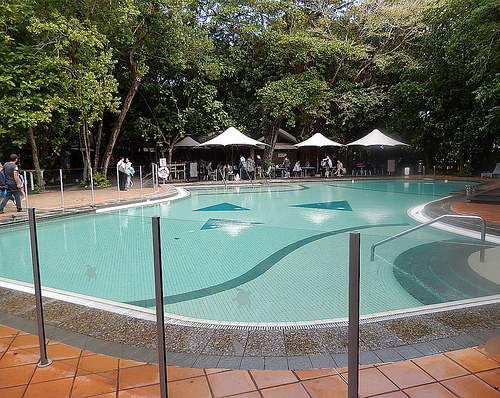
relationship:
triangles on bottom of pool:
[202, 217, 264, 234] [1, 176, 500, 337]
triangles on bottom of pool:
[192, 199, 254, 215] [1, 176, 500, 337]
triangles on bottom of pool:
[290, 198, 357, 218] [1, 176, 500, 337]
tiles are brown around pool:
[1, 326, 499, 397] [1, 176, 500, 337]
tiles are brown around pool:
[454, 200, 500, 222] [1, 176, 500, 337]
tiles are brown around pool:
[410, 170, 498, 189] [1, 176, 500, 337]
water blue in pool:
[1, 183, 496, 322] [1, 176, 500, 337]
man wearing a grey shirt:
[2, 152, 32, 214] [5, 163, 19, 187]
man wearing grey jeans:
[2, 152, 32, 214] [0, 187, 22, 214]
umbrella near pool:
[199, 125, 269, 176] [1, 176, 500, 337]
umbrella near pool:
[174, 129, 200, 170] [1, 176, 500, 337]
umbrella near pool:
[297, 127, 346, 177] [1, 176, 500, 337]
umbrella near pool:
[349, 126, 408, 176] [1, 176, 500, 337]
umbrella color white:
[174, 129, 200, 170] [225, 133, 242, 141]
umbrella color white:
[297, 127, 346, 177] [225, 133, 242, 141]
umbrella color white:
[349, 126, 408, 176] [225, 133, 242, 141]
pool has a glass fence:
[1, 176, 500, 337] [2, 209, 500, 397]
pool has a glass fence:
[1, 176, 500, 337] [6, 164, 162, 205]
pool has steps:
[1, 176, 500, 337] [398, 230, 499, 302]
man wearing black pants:
[117, 158, 130, 190] [119, 173, 128, 193]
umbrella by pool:
[174, 129, 200, 170] [1, 176, 500, 337]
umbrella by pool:
[199, 125, 269, 176] [1, 176, 500, 337]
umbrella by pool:
[297, 127, 346, 177] [1, 176, 500, 337]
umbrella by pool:
[349, 126, 408, 176] [1, 176, 500, 337]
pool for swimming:
[1, 176, 500, 337] [186, 195, 363, 286]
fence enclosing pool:
[2, 209, 500, 397] [1, 176, 500, 337]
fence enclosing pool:
[6, 164, 162, 205] [1, 176, 500, 337]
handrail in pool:
[366, 211, 490, 264] [1, 176, 500, 337]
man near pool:
[117, 157, 129, 191] [1, 176, 500, 337]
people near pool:
[2, 152, 32, 214] [1, 176, 500, 337]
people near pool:
[178, 153, 352, 179] [1, 176, 500, 337]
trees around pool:
[0, 4, 500, 178] [1, 176, 500, 337]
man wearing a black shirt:
[2, 152, 32, 214] [5, 163, 19, 187]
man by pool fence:
[117, 157, 129, 191] [2, 209, 500, 397]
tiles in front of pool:
[1, 326, 499, 397] [1, 176, 500, 337]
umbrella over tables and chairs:
[297, 127, 346, 177] [294, 169, 304, 177]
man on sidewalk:
[117, 157, 129, 191] [1, 172, 164, 222]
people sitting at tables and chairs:
[178, 153, 352, 179] [174, 163, 399, 178]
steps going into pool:
[398, 230, 499, 302] [1, 176, 500, 337]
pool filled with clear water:
[1, 176, 500, 337] [1, 183, 496, 322]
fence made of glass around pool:
[6, 164, 162, 205] [1, 176, 500, 337]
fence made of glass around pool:
[2, 209, 500, 397] [1, 176, 500, 337]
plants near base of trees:
[81, 172, 107, 188] [0, 4, 500, 178]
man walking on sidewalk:
[2, 152, 32, 214] [1, 172, 164, 222]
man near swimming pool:
[117, 157, 129, 191] [1, 176, 500, 337]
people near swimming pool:
[178, 153, 352, 179] [1, 176, 500, 337]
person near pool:
[2, 152, 32, 214] [1, 176, 500, 337]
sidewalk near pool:
[1, 172, 164, 222] [1, 176, 500, 337]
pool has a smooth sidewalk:
[1, 176, 500, 337] [1, 172, 164, 222]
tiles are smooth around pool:
[1, 326, 499, 397] [1, 176, 500, 337]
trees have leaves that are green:
[0, 4, 500, 178] [20, 42, 53, 85]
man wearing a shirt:
[2, 152, 32, 214] [5, 163, 19, 187]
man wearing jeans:
[2, 154, 27, 214] [2, 187, 15, 209]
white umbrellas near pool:
[225, 133, 242, 141] [1, 176, 500, 337]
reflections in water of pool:
[217, 217, 252, 239] [1, 176, 500, 337]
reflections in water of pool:
[304, 207, 337, 228] [1, 176, 500, 337]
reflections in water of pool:
[359, 201, 393, 231] [1, 176, 500, 337]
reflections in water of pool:
[122, 202, 177, 221] [1, 176, 500, 337]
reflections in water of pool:
[395, 177, 436, 190] [1, 176, 500, 337]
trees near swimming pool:
[0, 4, 500, 178] [1, 176, 500, 337]